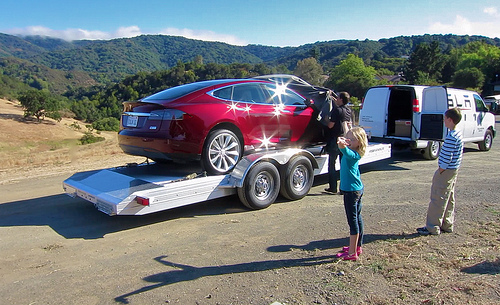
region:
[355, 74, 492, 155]
white van with the back door open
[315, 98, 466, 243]
two kids standing on side of road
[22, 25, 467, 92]
green trees covering the mountain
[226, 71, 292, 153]
sun shining off the side of the car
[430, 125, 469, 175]
blue and white striped shirt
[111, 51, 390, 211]
car on a white trailer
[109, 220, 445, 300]
shadow of two children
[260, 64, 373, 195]
a man covering the car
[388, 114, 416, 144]
cardboard box in back of van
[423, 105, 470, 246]
boy standing with his hands in his pocket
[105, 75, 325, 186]
red car on trailer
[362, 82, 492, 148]
white van with open door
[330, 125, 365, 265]
young girl in blue shirt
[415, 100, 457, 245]
young boy looking on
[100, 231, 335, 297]
girl making a shadow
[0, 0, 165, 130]
green mountain in the distance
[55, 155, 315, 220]
long white trailer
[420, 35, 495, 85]
green trees in background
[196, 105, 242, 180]
silver car wheel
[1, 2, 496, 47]
clouds in blue sky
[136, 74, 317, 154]
a sparkling magenta car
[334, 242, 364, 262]
little girl wearing pink shoes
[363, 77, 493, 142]
a white van parked in the middle of a road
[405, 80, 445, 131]
opened back door of a van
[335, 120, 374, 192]
blonde girl wearing a blue shirt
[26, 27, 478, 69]
green hills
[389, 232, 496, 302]
dead grass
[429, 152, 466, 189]
boy with his hand in his pocket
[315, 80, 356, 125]
man removing a black tarp on a car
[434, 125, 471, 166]
white and black striped shirt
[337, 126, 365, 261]
girl standing on the road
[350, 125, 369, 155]
blonde hair on the little girl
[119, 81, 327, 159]
shiny red car on the trailer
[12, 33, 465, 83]
the mountains in the distance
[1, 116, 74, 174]
the brown grass on the ground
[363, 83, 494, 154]
the big white truck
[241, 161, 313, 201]
the two tires on the trailer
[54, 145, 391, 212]
the long white trailer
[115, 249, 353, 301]
the shadow of the girl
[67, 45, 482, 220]
Red car is being towed.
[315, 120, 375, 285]
A little girl near the red car.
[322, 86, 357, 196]
Man standing near the red car.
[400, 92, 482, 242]
Boy in white shirt with blue stripes.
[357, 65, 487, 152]
A white van.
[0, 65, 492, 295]
Vehicles on a dirt road.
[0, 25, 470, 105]
Mountains covered in green trees.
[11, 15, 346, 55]
Clouds peeking above the mountains.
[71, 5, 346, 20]
Part of the sky is blue.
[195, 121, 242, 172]
The back wheel on a red car.